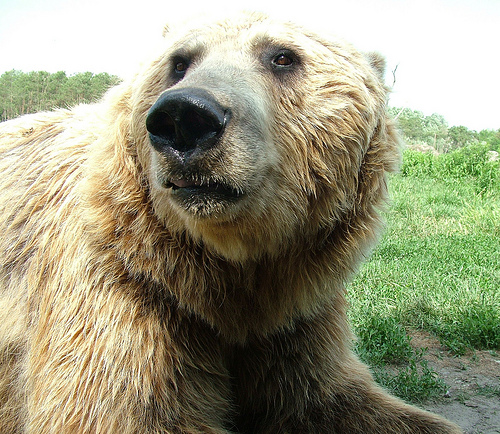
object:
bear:
[1, 10, 460, 434]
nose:
[144, 88, 227, 148]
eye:
[270, 50, 295, 68]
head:
[114, 8, 397, 267]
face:
[146, 31, 317, 227]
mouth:
[162, 169, 233, 204]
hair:
[4, 8, 455, 433]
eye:
[170, 56, 189, 73]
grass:
[354, 148, 499, 400]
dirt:
[366, 316, 499, 432]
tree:
[0, 55, 499, 155]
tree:
[0, 76, 7, 118]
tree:
[45, 74, 58, 113]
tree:
[59, 74, 72, 113]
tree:
[84, 76, 96, 103]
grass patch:
[401, 388, 414, 398]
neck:
[106, 74, 376, 323]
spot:
[279, 56, 285, 63]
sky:
[1, 2, 500, 138]